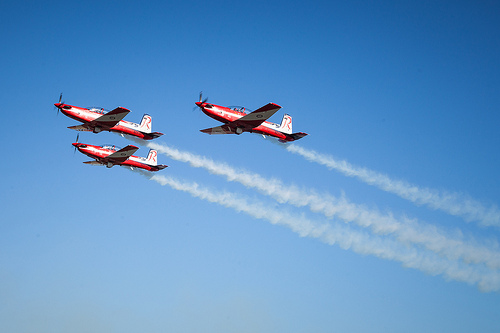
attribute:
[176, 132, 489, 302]
smoke — grouped, white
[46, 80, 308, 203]
planes — red, flying, small, white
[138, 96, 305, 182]
tails — white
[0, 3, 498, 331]
sky — clear, blue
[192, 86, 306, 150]
plane — red, flying